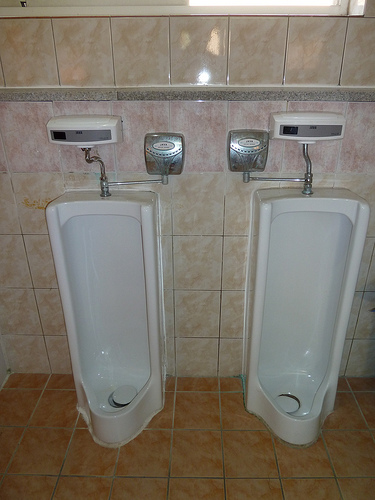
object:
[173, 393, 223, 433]
tile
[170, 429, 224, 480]
tile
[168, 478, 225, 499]
tile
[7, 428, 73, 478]
tile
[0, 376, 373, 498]
floor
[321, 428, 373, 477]
tile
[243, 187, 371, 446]
urinal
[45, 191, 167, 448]
urinal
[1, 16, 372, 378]
wall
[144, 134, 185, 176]
panel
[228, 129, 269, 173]
panel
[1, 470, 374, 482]
grout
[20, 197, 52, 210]
corrosion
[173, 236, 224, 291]
tile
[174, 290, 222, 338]
tile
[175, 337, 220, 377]
tile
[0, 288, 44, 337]
tile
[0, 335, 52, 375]
tile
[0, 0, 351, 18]
frame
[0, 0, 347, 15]
window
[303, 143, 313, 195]
pipe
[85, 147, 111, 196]
pipe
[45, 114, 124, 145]
tank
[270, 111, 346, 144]
tank